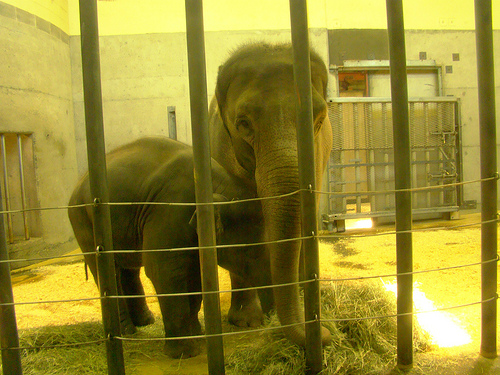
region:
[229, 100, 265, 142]
the elephant has an eye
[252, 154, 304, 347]
the elephant has a trunk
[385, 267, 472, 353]
the light is glaring off of theground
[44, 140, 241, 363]
the elephant is leaning over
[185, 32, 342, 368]
the elephant is standing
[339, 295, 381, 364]
the hay is brown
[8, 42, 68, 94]
the wall is gray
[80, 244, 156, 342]
the elephant has hind legs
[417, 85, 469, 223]
the door is metal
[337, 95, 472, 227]
the door is closed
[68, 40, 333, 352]
two gray elephants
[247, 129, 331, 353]
large trunk of elephant in the right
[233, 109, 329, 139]
two little black eyes of elephant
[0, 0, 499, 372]
gray bars with gray wire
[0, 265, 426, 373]
bunch of straw in the floor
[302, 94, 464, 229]
gray metal fence in the back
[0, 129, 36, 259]
two small gray bars in the wall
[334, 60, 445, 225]
thick gray metal door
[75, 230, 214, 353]
legs of baby elephant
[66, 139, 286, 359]
baby elephant standing next to big elephant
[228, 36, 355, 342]
elephant in a cage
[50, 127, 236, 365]
elephant in a cage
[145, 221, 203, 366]
leg of an elephant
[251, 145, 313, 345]
trunk of an elephant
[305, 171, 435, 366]
fence of a cage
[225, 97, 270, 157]
eye of an elephant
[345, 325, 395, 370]
hay inside of a cage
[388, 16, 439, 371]
bar of a cage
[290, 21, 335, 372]
bar of a cage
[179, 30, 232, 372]
bar of a cage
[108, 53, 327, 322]
two elephants in cage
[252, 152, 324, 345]
elephant has long trunk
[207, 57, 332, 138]
elephant's ears are folded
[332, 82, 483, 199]
grey fence on cage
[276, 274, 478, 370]
green grass on ground near elephants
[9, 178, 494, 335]
grey wires on cage bars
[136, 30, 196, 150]
grey walls in cage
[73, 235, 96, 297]
elephant has short tail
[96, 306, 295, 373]
elephants standing on grass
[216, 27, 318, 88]
hairs on head of older elephant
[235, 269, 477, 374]
Straw is on the ground.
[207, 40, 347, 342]
The elephant is eating the straw.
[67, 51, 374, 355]
two elephants standing.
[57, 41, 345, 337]
The elephants are grey.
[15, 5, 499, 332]
The elephants are in a cage.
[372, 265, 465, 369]
The light is shining through.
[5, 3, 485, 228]
The wall is grey.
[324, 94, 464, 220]
The gate is grey.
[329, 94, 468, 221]
The gate is metal.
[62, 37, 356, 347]
The elephants are eating.